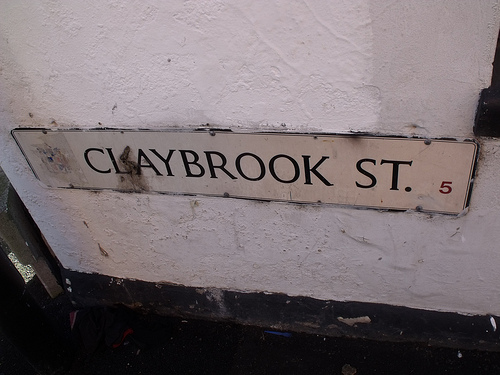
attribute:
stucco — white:
[1, 0, 389, 306]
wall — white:
[0, 0, 499, 353]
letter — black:
[81, 144, 111, 175]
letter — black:
[104, 144, 133, 177]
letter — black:
[132, 148, 163, 177]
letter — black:
[150, 147, 177, 177]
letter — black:
[177, 146, 205, 177]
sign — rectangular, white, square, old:
[11, 120, 478, 218]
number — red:
[438, 179, 453, 194]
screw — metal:
[207, 126, 217, 136]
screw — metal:
[222, 192, 231, 199]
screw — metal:
[423, 135, 434, 147]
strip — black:
[61, 258, 499, 348]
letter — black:
[202, 148, 238, 180]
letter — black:
[235, 152, 265, 182]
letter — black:
[302, 151, 336, 189]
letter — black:
[379, 150, 413, 194]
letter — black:
[352, 154, 379, 187]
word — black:
[84, 143, 339, 188]